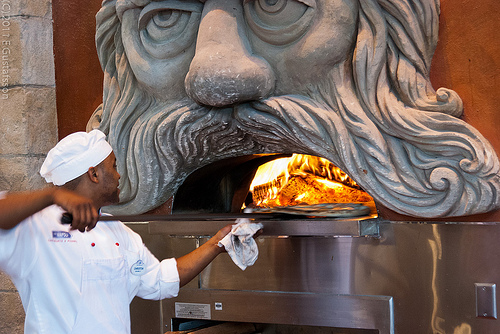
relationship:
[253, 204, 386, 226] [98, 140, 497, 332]
pizza inside oven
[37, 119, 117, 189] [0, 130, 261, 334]
chef hat on man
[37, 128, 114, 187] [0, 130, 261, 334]
chef hat on man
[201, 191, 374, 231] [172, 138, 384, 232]
stick in oven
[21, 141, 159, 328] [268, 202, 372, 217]
man putting pizza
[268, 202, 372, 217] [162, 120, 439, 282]
pizza in oven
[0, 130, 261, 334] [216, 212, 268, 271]
man holding white rag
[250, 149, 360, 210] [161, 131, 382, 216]
fire in oven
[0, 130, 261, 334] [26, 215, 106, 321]
man wearing uniform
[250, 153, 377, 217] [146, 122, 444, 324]
fire inside oven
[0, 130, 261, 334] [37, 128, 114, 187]
man wearing chef hat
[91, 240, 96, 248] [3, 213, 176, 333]
button on uniform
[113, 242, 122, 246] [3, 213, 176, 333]
button on uniform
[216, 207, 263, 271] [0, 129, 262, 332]
rag used by chef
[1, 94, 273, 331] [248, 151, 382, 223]
chef cooking pizza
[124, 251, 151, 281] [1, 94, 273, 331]
tag worn by chef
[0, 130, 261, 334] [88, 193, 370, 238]
man taking pan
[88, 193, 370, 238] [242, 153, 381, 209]
pan out of fire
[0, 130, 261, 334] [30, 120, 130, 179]
man wearing hat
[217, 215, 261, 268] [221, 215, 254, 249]
napkin in hand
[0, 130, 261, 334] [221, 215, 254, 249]
man has hand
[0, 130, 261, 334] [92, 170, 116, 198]
man with skin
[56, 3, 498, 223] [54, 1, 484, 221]
oven against wall